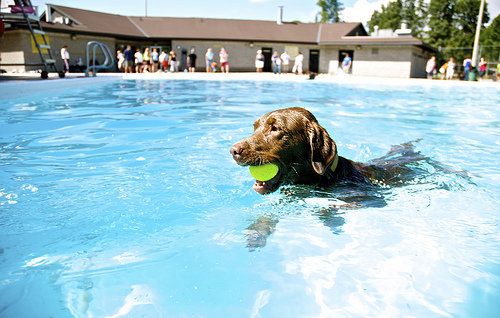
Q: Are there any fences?
A: No, there are no fences.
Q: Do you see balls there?
A: Yes, there is a ball.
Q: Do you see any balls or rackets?
A: Yes, there is a ball.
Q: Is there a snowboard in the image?
A: No, there are no snowboards.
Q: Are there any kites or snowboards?
A: No, there are no snowboards or kites.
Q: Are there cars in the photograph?
A: No, there are no cars.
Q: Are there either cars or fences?
A: No, there are no cars or fences.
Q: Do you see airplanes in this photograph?
A: No, there are no airplanes.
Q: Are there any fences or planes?
A: No, there are no planes or fences.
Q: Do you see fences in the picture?
A: No, there are no fences.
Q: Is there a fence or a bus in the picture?
A: No, there are no fences or buses.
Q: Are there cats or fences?
A: No, there are no fences or cats.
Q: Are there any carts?
A: No, there are no carts.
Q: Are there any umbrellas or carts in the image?
A: No, there are no carts or umbrellas.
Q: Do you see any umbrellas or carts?
A: No, there are no carts or umbrellas.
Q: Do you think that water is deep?
A: Yes, the water is deep.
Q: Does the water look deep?
A: Yes, the water is deep.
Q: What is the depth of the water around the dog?
A: The water is deep.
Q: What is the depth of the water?
A: The water is deep.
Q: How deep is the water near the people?
A: The water is deep.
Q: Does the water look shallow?
A: No, the water is deep.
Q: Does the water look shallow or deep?
A: The water is deep.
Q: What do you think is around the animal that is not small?
A: The water is around the dog.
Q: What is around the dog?
A: The water is around the dog.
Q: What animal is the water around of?
A: The water is around the dog.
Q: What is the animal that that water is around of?
A: The animal is a dog.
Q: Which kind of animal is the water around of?
A: The water is around the dog.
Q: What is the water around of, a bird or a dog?
A: The water is around a dog.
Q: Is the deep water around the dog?
A: Yes, the water is around the dog.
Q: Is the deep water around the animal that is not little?
A: Yes, the water is around the dog.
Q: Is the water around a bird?
A: No, the water is around the dog.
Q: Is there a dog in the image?
A: Yes, there is a dog.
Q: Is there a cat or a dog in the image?
A: Yes, there is a dog.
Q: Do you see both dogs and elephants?
A: No, there is a dog but no elephants.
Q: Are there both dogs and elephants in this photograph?
A: No, there is a dog but no elephants.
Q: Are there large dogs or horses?
A: Yes, there is a large dog.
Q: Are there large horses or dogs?
A: Yes, there is a large dog.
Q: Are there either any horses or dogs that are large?
A: Yes, the dog is large.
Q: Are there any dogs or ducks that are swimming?
A: Yes, the dog is swimming.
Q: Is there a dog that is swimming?
A: Yes, there is a dog that is swimming.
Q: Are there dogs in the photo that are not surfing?
A: Yes, there is a dog that is swimming.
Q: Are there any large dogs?
A: Yes, there is a large dog.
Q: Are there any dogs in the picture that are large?
A: Yes, there is a dog that is large.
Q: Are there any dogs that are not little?
A: Yes, there is a large dog.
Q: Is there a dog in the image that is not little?
A: Yes, there is a large dog.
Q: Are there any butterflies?
A: No, there are no butterflies.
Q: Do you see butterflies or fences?
A: No, there are no butterflies or fences.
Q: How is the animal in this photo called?
A: The animal is a dog.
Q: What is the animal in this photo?
A: The animal is a dog.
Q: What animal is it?
A: The animal is a dog.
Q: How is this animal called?
A: This is a dog.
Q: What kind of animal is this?
A: This is a dog.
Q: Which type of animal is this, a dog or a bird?
A: This is a dog.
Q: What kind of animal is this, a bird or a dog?
A: This is a dog.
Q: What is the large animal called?
A: The animal is a dog.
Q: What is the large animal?
A: The animal is a dog.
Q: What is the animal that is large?
A: The animal is a dog.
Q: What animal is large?
A: The animal is a dog.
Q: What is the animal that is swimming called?
A: The animal is a dog.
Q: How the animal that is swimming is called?
A: The animal is a dog.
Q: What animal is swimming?
A: The animal is a dog.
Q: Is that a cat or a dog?
A: That is a dog.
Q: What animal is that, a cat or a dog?
A: That is a dog.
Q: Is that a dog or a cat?
A: That is a dog.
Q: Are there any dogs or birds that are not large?
A: No, there is a dog but it is large.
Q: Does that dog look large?
A: Yes, the dog is large.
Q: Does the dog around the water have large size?
A: Yes, the dog is large.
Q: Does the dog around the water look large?
A: Yes, the dog is large.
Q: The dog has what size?
A: The dog is large.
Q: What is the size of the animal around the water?
A: The dog is large.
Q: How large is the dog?
A: The dog is large.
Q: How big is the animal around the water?
A: The dog is large.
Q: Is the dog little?
A: No, the dog is large.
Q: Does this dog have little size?
A: No, the dog is large.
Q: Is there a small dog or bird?
A: No, there is a dog but it is large.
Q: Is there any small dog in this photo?
A: No, there is a dog but it is large.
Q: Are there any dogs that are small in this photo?
A: No, there is a dog but it is large.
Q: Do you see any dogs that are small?
A: No, there is a dog but it is large.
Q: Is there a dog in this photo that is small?
A: No, there is a dog but it is large.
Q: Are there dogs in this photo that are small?
A: No, there is a dog but it is large.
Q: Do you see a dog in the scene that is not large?
A: No, there is a dog but it is large.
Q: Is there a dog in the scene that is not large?
A: No, there is a dog but it is large.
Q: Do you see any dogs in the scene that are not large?
A: No, there is a dog but it is large.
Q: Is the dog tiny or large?
A: The dog is large.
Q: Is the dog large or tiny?
A: The dog is large.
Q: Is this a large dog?
A: Yes, this is a large dog.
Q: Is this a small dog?
A: No, this is a large dog.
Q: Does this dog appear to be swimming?
A: Yes, the dog is swimming.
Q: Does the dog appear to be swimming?
A: Yes, the dog is swimming.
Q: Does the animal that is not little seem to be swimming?
A: Yes, the dog is swimming.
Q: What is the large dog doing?
A: The dog is swimming.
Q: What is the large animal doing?
A: The dog is swimming.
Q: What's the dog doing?
A: The dog is swimming.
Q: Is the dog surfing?
A: No, the dog is swimming.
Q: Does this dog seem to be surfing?
A: No, the dog is swimming.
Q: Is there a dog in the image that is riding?
A: No, there is a dog but it is swimming.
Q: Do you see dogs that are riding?
A: No, there is a dog but it is swimming.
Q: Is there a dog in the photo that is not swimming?
A: No, there is a dog but it is swimming.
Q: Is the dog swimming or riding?
A: The dog is swimming.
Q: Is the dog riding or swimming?
A: The dog is swimming.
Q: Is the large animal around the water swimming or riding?
A: The dog is swimming.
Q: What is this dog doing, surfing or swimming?
A: The dog is swimming.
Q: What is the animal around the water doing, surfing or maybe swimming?
A: The dog is swimming.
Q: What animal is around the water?
A: The dog is around the water.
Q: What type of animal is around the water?
A: The animal is a dog.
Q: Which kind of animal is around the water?
A: The animal is a dog.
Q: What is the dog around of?
A: The dog is around the water.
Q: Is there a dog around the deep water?
A: Yes, there is a dog around the water.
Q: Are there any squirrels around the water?
A: No, there is a dog around the water.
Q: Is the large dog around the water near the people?
A: Yes, the dog is around the water.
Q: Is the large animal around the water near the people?
A: Yes, the dog is around the water.